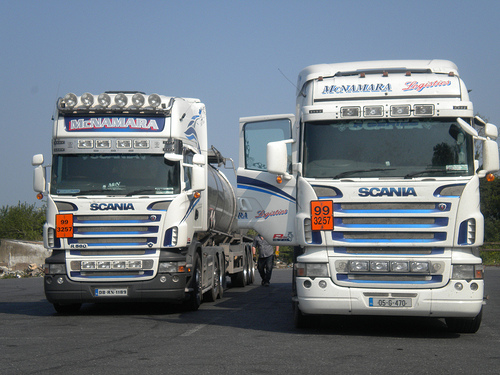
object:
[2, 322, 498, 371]
ground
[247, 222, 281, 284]
man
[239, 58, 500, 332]
truck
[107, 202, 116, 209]
blue letter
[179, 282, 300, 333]
shadow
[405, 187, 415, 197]
blue letter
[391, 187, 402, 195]
blue letter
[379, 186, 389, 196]
blue letter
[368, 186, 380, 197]
blue letter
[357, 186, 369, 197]
blue letter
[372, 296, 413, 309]
tag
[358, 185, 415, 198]
label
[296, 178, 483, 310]
front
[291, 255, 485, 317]
bumper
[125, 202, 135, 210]
letter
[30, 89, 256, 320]
truck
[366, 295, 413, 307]
license plate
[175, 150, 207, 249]
door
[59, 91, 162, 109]
top lights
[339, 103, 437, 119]
top lights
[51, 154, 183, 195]
window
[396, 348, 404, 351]
spot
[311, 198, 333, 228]
sign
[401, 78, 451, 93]
writing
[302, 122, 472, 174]
window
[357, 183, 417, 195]
lettering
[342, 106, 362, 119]
light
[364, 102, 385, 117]
light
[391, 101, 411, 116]
light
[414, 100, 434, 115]
light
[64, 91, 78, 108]
light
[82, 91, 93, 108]
light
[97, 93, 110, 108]
light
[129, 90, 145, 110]
light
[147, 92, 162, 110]
light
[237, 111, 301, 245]
door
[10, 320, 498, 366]
road